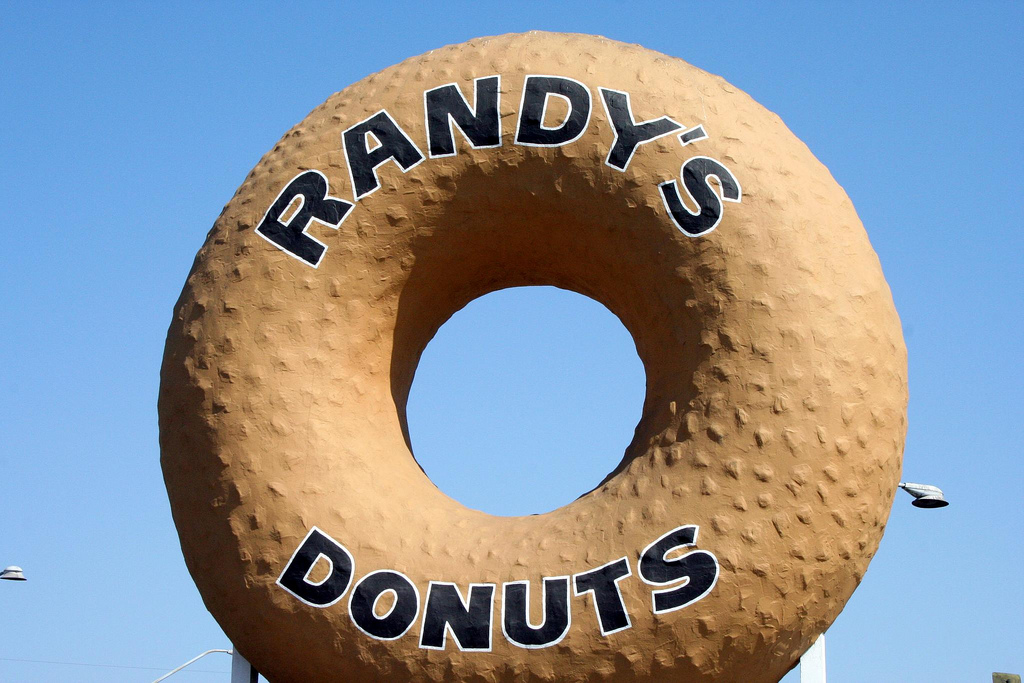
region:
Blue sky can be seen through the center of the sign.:
[299, 179, 767, 563]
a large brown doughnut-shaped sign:
[144, 19, 932, 680]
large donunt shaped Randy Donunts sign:
[136, 33, 915, 673]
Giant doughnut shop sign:
[139, 27, 955, 651]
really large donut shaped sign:
[157, 30, 908, 680]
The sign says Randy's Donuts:
[177, 38, 864, 678]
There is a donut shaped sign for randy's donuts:
[150, 37, 814, 677]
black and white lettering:
[255, 79, 750, 273]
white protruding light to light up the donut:
[878, 471, 978, 520]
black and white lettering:
[266, 518, 723, 656]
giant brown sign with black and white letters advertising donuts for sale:
[92, 26, 928, 681]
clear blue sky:
[31, 83, 187, 276]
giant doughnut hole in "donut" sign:
[351, 256, 718, 523]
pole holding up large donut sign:
[184, 642, 274, 681]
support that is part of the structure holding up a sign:
[787, 619, 874, 676]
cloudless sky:
[868, 57, 983, 184]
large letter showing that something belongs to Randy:
[246, 70, 772, 270]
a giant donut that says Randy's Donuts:
[141, 23, 935, 679]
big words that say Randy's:
[237, 64, 753, 306]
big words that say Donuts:
[255, 497, 733, 672]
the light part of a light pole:
[894, 460, 962, 517]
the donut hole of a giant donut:
[384, 250, 667, 527]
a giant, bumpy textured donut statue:
[144, 26, 935, 679]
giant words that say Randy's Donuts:
[224, 59, 766, 663]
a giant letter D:
[511, 58, 597, 166]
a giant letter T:
[572, 550, 636, 645]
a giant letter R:
[249, 162, 357, 271]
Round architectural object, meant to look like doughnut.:
[192, 79, 911, 674]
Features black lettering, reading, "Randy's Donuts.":
[220, 81, 828, 673]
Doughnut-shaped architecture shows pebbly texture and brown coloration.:
[104, 91, 882, 642]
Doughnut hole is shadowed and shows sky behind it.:
[360, 211, 741, 619]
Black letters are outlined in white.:
[183, 78, 812, 674]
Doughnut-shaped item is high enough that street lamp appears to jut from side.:
[771, 366, 994, 667]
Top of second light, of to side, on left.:
[0, 486, 76, 660]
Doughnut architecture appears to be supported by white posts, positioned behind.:
[158, 387, 901, 681]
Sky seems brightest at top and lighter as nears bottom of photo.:
[6, 12, 270, 676]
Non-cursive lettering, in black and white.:
[250, 132, 811, 349]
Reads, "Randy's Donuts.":
[272, 140, 740, 647]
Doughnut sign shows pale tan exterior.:
[254, 136, 902, 639]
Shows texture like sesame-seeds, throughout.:
[209, 215, 871, 627]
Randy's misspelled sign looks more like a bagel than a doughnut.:
[241, 137, 773, 634]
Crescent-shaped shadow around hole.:
[387, 190, 708, 549]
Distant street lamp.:
[11, 374, 103, 666]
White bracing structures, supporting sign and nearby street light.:
[137, 423, 1020, 661]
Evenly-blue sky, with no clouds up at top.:
[54, 29, 536, 185]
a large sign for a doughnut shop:
[158, 19, 911, 677]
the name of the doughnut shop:
[250, 75, 766, 654]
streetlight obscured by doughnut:
[900, 471, 970, 529]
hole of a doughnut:
[391, 256, 660, 522]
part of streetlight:
[6, 553, 39, 582]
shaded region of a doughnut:
[437, 162, 726, 448]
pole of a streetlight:
[794, 623, 830, 680]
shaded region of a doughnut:
[147, 311, 360, 678]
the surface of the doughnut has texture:
[725, 264, 897, 553]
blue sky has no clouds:
[4, 7, 210, 219]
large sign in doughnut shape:
[150, 19, 898, 677]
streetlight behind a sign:
[788, 462, 965, 675]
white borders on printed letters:
[279, 513, 350, 608]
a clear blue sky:
[51, 78, 178, 202]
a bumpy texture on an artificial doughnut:
[713, 402, 844, 529]